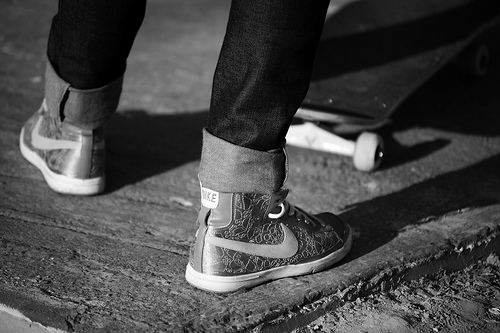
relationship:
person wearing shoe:
[20, 1, 355, 292] [18, 98, 108, 196]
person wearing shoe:
[20, 1, 355, 292] [182, 183, 353, 293]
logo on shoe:
[30, 114, 80, 153] [18, 98, 108, 196]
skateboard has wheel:
[283, 1, 498, 173] [353, 131, 384, 174]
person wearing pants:
[20, 1, 355, 292] [44, 1, 328, 194]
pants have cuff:
[44, 1, 328, 194] [44, 62, 125, 126]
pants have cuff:
[44, 1, 328, 194] [200, 126, 287, 195]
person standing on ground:
[20, 1, 355, 292] [1, 0, 499, 333]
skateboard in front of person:
[283, 1, 498, 173] [20, 1, 355, 292]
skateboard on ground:
[283, 1, 498, 173] [1, 0, 499, 333]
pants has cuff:
[44, 1, 328, 194] [44, 62, 125, 126]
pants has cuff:
[44, 1, 328, 194] [200, 126, 287, 195]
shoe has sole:
[18, 98, 108, 196] [19, 127, 104, 194]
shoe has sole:
[182, 183, 353, 293] [184, 224, 353, 291]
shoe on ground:
[18, 98, 108, 196] [1, 0, 499, 333]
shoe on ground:
[182, 183, 353, 293] [1, 0, 499, 333]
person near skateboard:
[20, 1, 355, 292] [283, 1, 498, 173]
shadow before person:
[87, 2, 498, 275] [20, 1, 355, 292]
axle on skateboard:
[286, 122, 357, 159] [283, 1, 498, 173]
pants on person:
[44, 1, 328, 194] [20, 1, 355, 292]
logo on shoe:
[214, 223, 300, 261] [182, 183, 353, 293]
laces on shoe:
[266, 200, 326, 230] [182, 183, 353, 293]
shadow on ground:
[87, 2, 498, 275] [1, 0, 499, 333]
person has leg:
[20, 1, 355, 292] [46, 2, 149, 126]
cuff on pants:
[44, 62, 125, 126] [44, 1, 328, 194]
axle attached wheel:
[286, 122, 357, 159] [353, 131, 384, 174]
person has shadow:
[20, 1, 355, 292] [87, 2, 498, 275]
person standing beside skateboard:
[20, 1, 355, 292] [283, 1, 498, 173]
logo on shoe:
[200, 187, 220, 208] [182, 183, 353, 293]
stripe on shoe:
[76, 129, 94, 179] [18, 98, 108, 196]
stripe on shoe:
[193, 205, 209, 273] [182, 183, 353, 293]